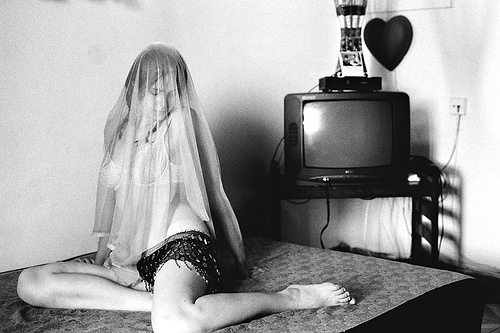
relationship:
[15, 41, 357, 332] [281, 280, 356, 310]
girl has foot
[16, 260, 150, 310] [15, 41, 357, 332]
leg of a girl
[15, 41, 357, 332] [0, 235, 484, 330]
girl on bed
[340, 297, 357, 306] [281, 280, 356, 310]
toe on foot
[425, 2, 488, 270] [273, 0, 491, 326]
shadow on wall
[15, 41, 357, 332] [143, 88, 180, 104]
girl has eyes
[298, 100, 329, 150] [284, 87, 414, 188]
light on tv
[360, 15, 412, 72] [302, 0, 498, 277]
heart on wall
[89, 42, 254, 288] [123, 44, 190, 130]
veil on woman's head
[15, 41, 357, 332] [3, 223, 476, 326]
girl sitting on bed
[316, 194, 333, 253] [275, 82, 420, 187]
cord hooked to tv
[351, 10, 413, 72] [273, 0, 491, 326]
heart on wall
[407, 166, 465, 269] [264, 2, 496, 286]
shadow are on wall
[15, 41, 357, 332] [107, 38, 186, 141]
girl has hair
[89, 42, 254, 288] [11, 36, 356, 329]
veil on girl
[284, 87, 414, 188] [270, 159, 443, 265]
tv on stand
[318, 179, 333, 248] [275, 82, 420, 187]
cord on tv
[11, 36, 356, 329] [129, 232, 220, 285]
girl wearing shorts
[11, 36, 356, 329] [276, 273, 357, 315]
girl has foot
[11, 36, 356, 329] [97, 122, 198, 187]
girl wearing bra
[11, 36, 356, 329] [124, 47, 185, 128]
girl has head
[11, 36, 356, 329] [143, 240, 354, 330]
girl has leg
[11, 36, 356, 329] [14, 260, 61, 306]
girl has knee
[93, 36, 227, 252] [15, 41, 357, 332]
veil on girl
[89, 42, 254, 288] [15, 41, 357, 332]
veil on girl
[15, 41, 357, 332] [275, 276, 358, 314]
girl has foot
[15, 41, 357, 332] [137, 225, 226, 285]
girl wears shorts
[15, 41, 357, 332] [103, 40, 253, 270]
girl has veil